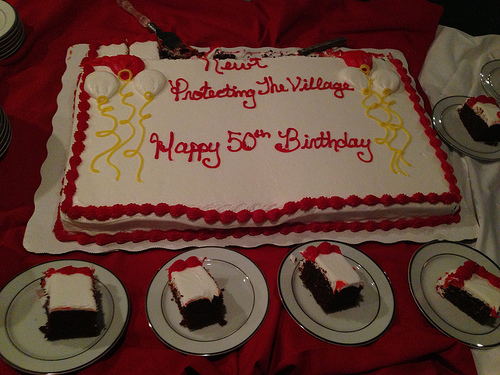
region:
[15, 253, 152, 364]
a small piece of cake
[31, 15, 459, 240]
a large white sheet cake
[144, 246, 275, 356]
a small white china plate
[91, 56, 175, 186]
balloons made out of frosting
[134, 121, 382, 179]
a happy birthday message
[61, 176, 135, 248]
a red icing border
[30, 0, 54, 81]
a red cloth table cover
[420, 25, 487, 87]
a white cloth napkin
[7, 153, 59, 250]
a large cardboard cake holder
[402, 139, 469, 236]
the corner piece of a sheet cake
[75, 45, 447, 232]
the cake on the table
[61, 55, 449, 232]
the cake is decorated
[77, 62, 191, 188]
balloons on the cake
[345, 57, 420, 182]
balloons on the cake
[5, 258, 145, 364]
the cake on the plate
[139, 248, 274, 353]
the cake on the plate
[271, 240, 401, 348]
the cake on the plate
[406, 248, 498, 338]
the cake on the plate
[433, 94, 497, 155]
the cake on the plate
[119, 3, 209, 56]
the utensil beside the cake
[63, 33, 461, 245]
this is a cake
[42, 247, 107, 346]
this is a slice of cake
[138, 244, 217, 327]
this is a slice of cake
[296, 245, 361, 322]
this is a slice of cake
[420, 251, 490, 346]
this is a slice of cake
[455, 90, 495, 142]
this is a slice of cake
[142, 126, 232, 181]
a word on the birthday cake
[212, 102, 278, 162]
a word on the birthday cake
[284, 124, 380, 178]
a word on the birthday cake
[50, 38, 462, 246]
Red and white 50th birthday cake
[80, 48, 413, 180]
Red and white balloons on a cake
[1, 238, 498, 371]
Row of pieces of cake on plates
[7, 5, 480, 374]
Red tablecloth under a birthday cake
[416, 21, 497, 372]
White tablecloth on a table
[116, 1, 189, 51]
Cake cutter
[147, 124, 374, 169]
Happy 50th Birthday wording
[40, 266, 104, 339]
Chocolate cake with red and white frosting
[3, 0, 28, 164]
Two stacks of white plates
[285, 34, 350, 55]
Handle of a knife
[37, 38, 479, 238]
Cake on a platter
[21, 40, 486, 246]
Cake is on a platter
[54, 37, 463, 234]
Cake is covered in frosting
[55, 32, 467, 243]
Cake covered in frosting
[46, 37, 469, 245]
Cake covered in red and white frosting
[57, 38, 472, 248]
Cake is covered in red and white frosting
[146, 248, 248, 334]
Cake on a plate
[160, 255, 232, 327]
Cake is on a plate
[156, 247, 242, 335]
Cake on a white plate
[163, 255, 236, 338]
Cake is on a white plate